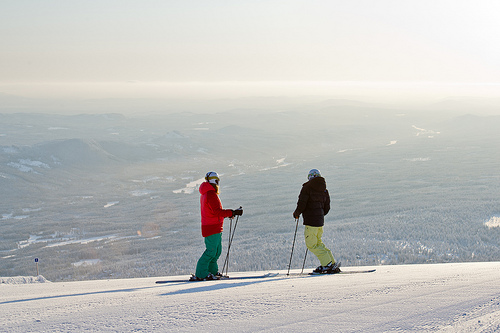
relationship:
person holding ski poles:
[194, 168, 248, 278] [220, 205, 242, 275]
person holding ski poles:
[292, 167, 343, 276] [298, 246, 308, 273]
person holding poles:
[292, 167, 343, 276] [287, 218, 299, 275]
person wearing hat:
[292, 167, 343, 276] [307, 168, 321, 180]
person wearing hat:
[194, 168, 248, 278] [205, 171, 219, 184]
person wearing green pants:
[195, 171, 243, 278] [193, 229, 225, 277]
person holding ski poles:
[195, 171, 243, 278] [265, 213, 332, 268]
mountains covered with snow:
[5, 97, 498, 271] [7, 135, 499, 255]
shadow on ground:
[165, 287, 229, 294] [348, 282, 443, 321]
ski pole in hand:
[224, 221, 236, 278] [233, 205, 244, 216]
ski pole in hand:
[225, 218, 233, 275] [227, 204, 234, 219]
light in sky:
[380, 5, 495, 63] [9, 4, 495, 81]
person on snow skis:
[195, 171, 243, 278] [154, 249, 404, 301]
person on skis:
[194, 168, 248, 278] [153, 267, 284, 287]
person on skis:
[195, 171, 243, 278] [152, 262, 279, 289]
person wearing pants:
[195, 171, 243, 278] [192, 230, 239, 285]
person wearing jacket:
[195, 171, 243, 278] [291, 177, 342, 219]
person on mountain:
[292, 168, 341, 276] [9, 282, 493, 331]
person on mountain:
[195, 171, 243, 278] [9, 282, 493, 331]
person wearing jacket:
[195, 171, 243, 278] [199, 182, 233, 235]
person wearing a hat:
[195, 171, 243, 278] [204, 169, 215, 179]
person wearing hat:
[292, 168, 341, 276] [306, 170, 323, 180]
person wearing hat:
[195, 171, 243, 278] [205, 170, 220, 184]